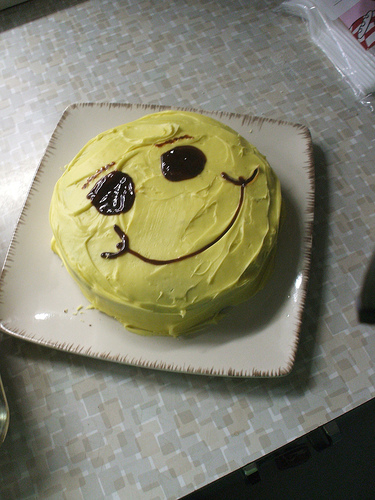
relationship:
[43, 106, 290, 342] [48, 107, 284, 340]
cake has frosting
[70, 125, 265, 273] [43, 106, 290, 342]
smiley face on cake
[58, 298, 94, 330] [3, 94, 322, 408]
crumbs on plate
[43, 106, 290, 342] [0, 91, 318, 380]
cake on a plate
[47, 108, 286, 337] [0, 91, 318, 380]
cake on a plate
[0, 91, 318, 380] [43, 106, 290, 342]
plate with a cake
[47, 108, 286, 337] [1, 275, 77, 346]
cake on plate